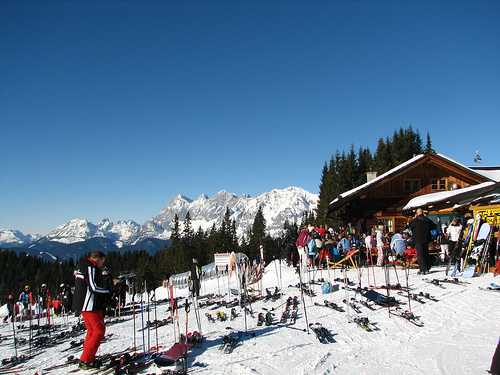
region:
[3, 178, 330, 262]
mountains behind the ski lodge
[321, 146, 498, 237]
a building on the ski slope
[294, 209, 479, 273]
a crowd in front of the ski slope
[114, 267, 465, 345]
skies on the slope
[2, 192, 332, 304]
trees in front of the mountains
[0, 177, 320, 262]
snow on the mountains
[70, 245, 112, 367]
a man getting skies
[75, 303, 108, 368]
the man is wearing pants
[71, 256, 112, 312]
the man is wearing a jacket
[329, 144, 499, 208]
snow on the roof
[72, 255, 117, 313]
man wears black and white coat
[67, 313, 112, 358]
man is wearing red pants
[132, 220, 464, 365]
numerous pairs of skis on snow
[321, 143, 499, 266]
tall and brown lodge on right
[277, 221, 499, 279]
numerous people are outside lodge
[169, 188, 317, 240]
white and grey mountain in distance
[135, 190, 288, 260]
tall and green pine trees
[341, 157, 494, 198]
white snow is on lodge roof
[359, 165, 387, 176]
grey chimney on lodge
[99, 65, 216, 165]
sky is blue and cloudless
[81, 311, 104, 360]
red padded snow pants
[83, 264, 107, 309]
black and white jacket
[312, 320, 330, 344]
black skis on snow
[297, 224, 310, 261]
person wearing red coat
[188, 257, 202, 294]
person wearing black jacket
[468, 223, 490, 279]
blue snow board on wall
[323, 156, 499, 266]
brown wooden cabin building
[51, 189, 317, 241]
snow covered mountain top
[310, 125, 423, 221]
green trees by building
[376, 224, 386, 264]
person wearing white snow suit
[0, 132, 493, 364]
people in the ski resort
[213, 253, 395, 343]
skis and poles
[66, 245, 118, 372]
a man wearing red snow pants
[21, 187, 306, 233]
mountains in the background covered with snow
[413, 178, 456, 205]
a roof covered with snow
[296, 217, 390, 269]
a group of people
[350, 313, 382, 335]
pair of skis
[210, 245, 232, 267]
a sign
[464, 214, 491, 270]
pile of snowboards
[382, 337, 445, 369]
snow on the ground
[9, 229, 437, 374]
the poles are stuck in the snow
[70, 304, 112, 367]
the man is wearing red pants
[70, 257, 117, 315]
the man's jacket is black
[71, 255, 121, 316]
the jacket has white stripes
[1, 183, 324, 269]
the mountains are in the distance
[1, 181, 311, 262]
the mountains have snow on them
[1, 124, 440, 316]
the trees are evergreen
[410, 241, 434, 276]
the man is wearing black pants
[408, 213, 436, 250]
the man is wearing a black jacket